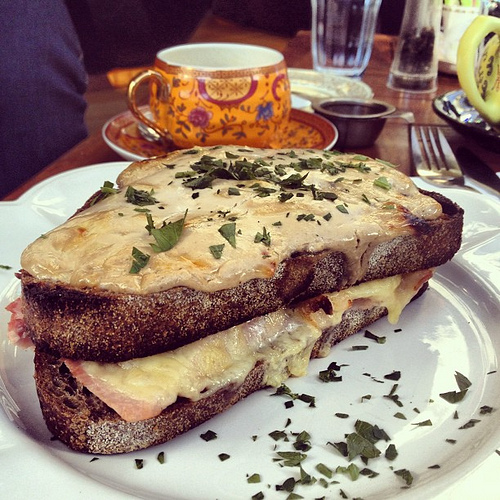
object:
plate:
[0, 160, 497, 499]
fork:
[410, 124, 482, 194]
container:
[311, 97, 396, 148]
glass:
[310, 0, 379, 76]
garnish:
[347, 430, 381, 461]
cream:
[50, 233, 114, 271]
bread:
[19, 144, 465, 361]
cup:
[126, 42, 290, 149]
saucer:
[102, 101, 340, 161]